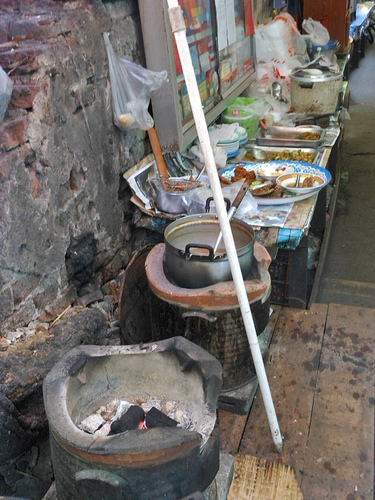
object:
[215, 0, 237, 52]
papers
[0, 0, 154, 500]
wall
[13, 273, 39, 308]
bricks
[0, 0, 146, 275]
cement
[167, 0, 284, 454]
pole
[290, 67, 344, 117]
pot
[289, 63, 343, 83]
lid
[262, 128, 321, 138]
ground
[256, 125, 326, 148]
pan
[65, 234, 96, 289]
break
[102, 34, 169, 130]
bag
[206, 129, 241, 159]
plates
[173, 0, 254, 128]
glass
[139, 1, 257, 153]
bulletin board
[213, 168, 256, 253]
spoon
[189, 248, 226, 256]
soup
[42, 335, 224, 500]
fireplace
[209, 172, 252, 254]
laddle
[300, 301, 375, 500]
wood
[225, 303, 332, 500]
planks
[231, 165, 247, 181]
food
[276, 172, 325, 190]
bowl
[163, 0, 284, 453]
stick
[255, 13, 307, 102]
bag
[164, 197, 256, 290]
pot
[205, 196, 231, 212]
handles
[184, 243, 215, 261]
handles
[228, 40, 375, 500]
ground